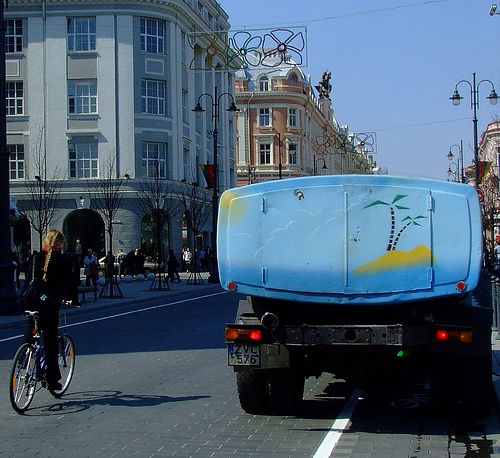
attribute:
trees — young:
[11, 131, 216, 285]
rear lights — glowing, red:
[221, 321, 478, 348]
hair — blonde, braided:
[35, 217, 65, 289]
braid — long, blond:
[41, 235, 55, 284]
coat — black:
[21, 249, 78, 305]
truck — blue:
[170, 117, 498, 436]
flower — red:
[366, 184, 426, 255]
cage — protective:
[142, 256, 173, 286]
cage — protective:
[99, 271, 126, 298]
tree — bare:
[91, 152, 123, 264]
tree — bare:
[137, 160, 183, 259]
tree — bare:
[176, 171, 213, 253]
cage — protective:
[192, 250, 212, 287]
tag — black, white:
[227, 340, 265, 366]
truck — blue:
[215, 172, 497, 415]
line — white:
[280, 383, 367, 454]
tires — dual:
[238, 369, 304, 409]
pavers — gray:
[220, 416, 311, 453]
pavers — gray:
[121, 405, 230, 452]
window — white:
[145, 80, 166, 124]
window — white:
[4, 17, 25, 57]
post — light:
[174, 76, 253, 299]